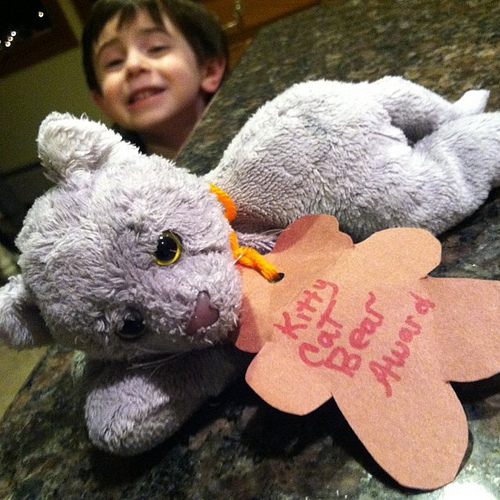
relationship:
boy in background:
[80, 0, 229, 158] [168, 50, 275, 137]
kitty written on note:
[157, 292, 383, 344] [232, 214, 499, 490]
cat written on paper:
[298, 300, 343, 367] [299, 299, 343, 439]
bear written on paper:
[324, 291, 386, 378] [236, 213, 498, 490]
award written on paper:
[379, 291, 437, 464] [230, 214, 472, 464]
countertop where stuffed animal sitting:
[3, 2, 498, 498] [202, 376, 244, 437]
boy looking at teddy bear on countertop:
[80, 0, 229, 158] [86, 335, 171, 439]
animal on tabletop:
[18, 87, 470, 346] [15, 78, 497, 498]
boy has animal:
[80, 0, 229, 158] [0, 74, 500, 456]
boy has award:
[80, 0, 229, 158] [274, 279, 434, 399]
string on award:
[209, 182, 283, 281] [7, 47, 489, 452]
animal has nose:
[0, 74, 500, 456] [185, 289, 225, 329]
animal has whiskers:
[0, 74, 500, 456] [123, 341, 203, 387]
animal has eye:
[0, 74, 500, 456] [149, 227, 184, 265]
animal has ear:
[0, 74, 500, 456] [33, 110, 126, 181]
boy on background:
[80, 23, 262, 142] [5, 11, 498, 90]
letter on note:
[272, 310, 305, 345] [240, 213, 499, 490]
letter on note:
[296, 339, 322, 369] [240, 213, 499, 490]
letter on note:
[367, 361, 402, 398] [240, 213, 499, 490]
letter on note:
[406, 288, 436, 315] [240, 213, 499, 490]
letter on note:
[361, 287, 388, 319] [240, 213, 499, 490]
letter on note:
[384, 342, 409, 369] [240, 213, 499, 490]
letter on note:
[365, 291, 386, 319] [240, 213, 499, 490]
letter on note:
[318, 300, 339, 327] [240, 213, 499, 490]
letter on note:
[323, 347, 363, 375] [240, 213, 499, 490]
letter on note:
[272, 310, 308, 340] [240, 213, 499, 490]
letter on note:
[380, 334, 415, 369] [230, 217, 485, 497]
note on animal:
[232, 214, 499, 490] [0, 74, 500, 456]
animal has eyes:
[0, 74, 500, 456] [96, 216, 186, 344]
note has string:
[232, 214, 499, 490] [203, 180, 279, 285]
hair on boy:
[79, 3, 230, 103] [79, 2, 229, 158]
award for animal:
[274, 279, 434, 399] [0, 74, 500, 456]